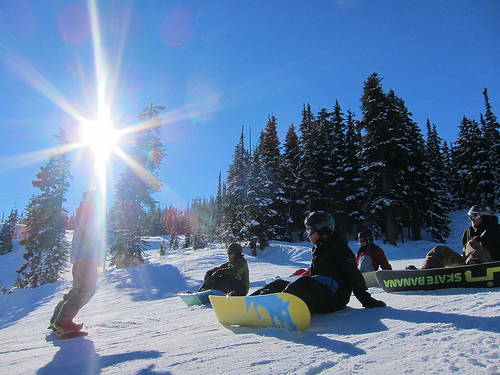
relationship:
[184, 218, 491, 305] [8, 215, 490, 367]
people on snow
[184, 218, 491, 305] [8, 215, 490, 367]
snow boarders on snow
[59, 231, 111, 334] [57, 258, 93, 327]
man wearing pants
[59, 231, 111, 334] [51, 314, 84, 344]
man has snowboard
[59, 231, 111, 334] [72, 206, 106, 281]
man wearing jacket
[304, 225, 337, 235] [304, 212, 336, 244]
goggles on head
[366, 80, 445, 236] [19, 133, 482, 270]
tree in background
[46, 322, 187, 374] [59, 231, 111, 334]
shadow of skiier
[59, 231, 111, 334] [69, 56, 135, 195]
snowboarder in sun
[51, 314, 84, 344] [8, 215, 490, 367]
snowboard in snow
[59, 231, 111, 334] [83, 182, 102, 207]
person wearing helmet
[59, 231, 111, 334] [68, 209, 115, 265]
man wearing coat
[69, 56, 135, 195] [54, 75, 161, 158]
sun generating circle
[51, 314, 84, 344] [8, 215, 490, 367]
heels above snow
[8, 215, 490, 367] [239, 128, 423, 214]
snow on branches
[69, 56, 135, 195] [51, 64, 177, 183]
sun has glare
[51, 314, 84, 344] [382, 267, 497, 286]
snowboard has writing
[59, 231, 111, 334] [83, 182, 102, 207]
man has helmet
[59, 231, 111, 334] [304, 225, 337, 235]
man wearing sunglasses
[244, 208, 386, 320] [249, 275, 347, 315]
man wearing pants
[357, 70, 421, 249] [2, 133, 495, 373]
tree covered in snow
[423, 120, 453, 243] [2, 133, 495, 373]
tree covered in snow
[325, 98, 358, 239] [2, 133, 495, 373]
tree covered in snow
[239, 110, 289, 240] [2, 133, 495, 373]
tree covered in snow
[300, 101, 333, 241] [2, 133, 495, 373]
tree covered in snow